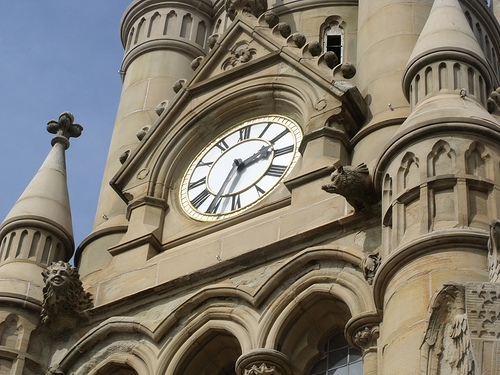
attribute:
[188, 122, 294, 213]
roman numerals — black, upside down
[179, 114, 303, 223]
clock — white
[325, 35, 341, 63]
window — small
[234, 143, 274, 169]
short hand — black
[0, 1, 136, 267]
sky — blue